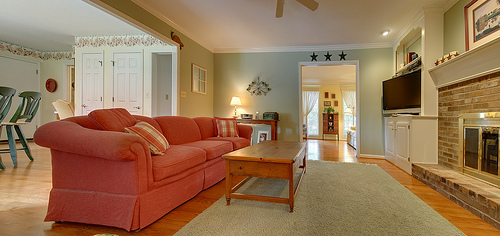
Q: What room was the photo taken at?
A: It was taken at the living room.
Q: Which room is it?
A: It is a living room.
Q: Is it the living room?
A: Yes, it is the living room.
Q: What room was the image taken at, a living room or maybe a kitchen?
A: It was taken at a living room.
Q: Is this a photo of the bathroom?
A: No, the picture is showing the living room.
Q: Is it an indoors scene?
A: Yes, it is indoors.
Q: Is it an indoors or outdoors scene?
A: It is indoors.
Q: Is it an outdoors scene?
A: No, it is indoors.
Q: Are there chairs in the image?
A: Yes, there is a chair.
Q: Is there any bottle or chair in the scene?
A: Yes, there is a chair.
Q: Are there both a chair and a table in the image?
A: Yes, there are both a chair and a table.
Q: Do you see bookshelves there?
A: No, there are no bookshelves.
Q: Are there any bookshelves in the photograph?
A: No, there are no bookshelves.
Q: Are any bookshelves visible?
A: No, there are no bookshelves.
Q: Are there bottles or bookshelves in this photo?
A: No, there are no bookshelves or bottles.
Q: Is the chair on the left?
A: Yes, the chair is on the left of the image.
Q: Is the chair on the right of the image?
A: No, the chair is on the left of the image.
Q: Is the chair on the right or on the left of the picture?
A: The chair is on the left of the image.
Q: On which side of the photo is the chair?
A: The chair is on the left of the image.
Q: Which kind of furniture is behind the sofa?
A: The piece of furniture is a chair.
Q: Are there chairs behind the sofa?
A: Yes, there is a chair behind the sofa.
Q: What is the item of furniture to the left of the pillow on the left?
A: The piece of furniture is a chair.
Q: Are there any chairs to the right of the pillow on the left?
A: No, the chair is to the left of the pillow.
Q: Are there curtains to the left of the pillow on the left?
A: No, there is a chair to the left of the pillow.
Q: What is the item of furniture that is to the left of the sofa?
A: The piece of furniture is a chair.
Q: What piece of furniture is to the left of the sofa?
A: The piece of furniture is a chair.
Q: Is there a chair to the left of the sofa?
A: Yes, there is a chair to the left of the sofa.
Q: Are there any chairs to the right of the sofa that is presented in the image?
A: No, the chair is to the left of the sofa.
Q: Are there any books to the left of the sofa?
A: No, there is a chair to the left of the sofa.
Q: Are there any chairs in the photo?
A: Yes, there is a chair.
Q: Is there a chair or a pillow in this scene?
A: Yes, there is a chair.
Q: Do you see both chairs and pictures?
A: Yes, there are both a chair and a picture.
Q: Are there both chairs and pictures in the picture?
A: Yes, there are both a chair and a picture.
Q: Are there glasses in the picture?
A: No, there are no glasses.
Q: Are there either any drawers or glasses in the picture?
A: No, there are no glasses or drawers.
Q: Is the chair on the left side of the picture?
A: Yes, the chair is on the left of the image.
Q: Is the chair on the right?
A: No, the chair is on the left of the image.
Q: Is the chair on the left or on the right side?
A: The chair is on the left of the image.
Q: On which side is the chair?
A: The chair is on the left of the image.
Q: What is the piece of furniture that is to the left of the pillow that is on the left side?
A: The piece of furniture is a chair.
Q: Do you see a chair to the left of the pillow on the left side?
A: Yes, there is a chair to the left of the pillow.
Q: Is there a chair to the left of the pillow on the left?
A: Yes, there is a chair to the left of the pillow.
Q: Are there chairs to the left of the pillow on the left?
A: Yes, there is a chair to the left of the pillow.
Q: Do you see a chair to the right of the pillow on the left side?
A: No, the chair is to the left of the pillow.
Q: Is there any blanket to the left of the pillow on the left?
A: No, there is a chair to the left of the pillow.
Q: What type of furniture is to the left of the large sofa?
A: The piece of furniture is a chair.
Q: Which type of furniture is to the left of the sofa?
A: The piece of furniture is a chair.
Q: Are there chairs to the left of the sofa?
A: Yes, there is a chair to the left of the sofa.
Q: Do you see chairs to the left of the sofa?
A: Yes, there is a chair to the left of the sofa.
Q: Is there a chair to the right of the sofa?
A: No, the chair is to the left of the sofa.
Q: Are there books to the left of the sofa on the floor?
A: No, there is a chair to the left of the sofa.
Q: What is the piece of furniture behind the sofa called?
A: The piece of furniture is a chair.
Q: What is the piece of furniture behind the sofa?
A: The piece of furniture is a chair.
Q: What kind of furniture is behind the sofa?
A: The piece of furniture is a chair.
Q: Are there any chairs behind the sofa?
A: Yes, there is a chair behind the sofa.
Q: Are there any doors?
A: Yes, there is a door.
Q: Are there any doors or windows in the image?
A: Yes, there is a door.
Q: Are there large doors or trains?
A: Yes, there is a large door.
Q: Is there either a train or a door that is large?
A: Yes, the door is large.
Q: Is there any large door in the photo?
A: Yes, there is a large door.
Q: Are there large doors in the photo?
A: Yes, there is a large door.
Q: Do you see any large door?
A: Yes, there is a large door.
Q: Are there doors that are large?
A: Yes, there is a door that is large.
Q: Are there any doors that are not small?
A: Yes, there is a large door.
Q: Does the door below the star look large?
A: Yes, the door is large.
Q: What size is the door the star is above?
A: The door is large.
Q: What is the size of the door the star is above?
A: The door is large.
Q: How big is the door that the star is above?
A: The door is large.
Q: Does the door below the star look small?
A: No, the door is large.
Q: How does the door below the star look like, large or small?
A: The door is large.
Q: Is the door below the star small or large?
A: The door is large.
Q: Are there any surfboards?
A: No, there are no surfboards.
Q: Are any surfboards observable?
A: No, there are no surfboards.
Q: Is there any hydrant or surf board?
A: No, there are no surfboards or fire hydrants.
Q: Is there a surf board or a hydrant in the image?
A: No, there are no surfboards or fire hydrants.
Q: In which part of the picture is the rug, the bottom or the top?
A: The rug is in the bottom of the image.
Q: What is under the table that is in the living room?
A: The rug is under the table.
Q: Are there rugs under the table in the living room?
A: Yes, there is a rug under the table.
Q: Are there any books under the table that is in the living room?
A: No, there is a rug under the table.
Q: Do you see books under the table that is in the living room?
A: No, there is a rug under the table.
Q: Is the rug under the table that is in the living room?
A: Yes, the rug is under the table.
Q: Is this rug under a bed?
A: No, the rug is under the table.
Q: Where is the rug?
A: The rug is on the floor.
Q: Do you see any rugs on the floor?
A: Yes, there is a rug on the floor.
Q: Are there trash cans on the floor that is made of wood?
A: No, there is a rug on the floor.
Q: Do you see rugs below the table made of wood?
A: Yes, there is a rug below the table.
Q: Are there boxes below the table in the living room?
A: No, there is a rug below the table.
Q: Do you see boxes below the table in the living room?
A: No, there is a rug below the table.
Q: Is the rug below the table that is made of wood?
A: Yes, the rug is below the table.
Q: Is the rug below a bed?
A: No, the rug is below the table.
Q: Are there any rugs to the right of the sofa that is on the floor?
A: Yes, there is a rug to the right of the sofa.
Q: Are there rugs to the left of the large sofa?
A: No, the rug is to the right of the sofa.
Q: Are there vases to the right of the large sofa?
A: No, there is a rug to the right of the sofa.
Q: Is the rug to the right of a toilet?
A: No, the rug is to the right of the sofa.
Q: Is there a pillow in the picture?
A: Yes, there is a pillow.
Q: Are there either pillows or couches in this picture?
A: Yes, there is a pillow.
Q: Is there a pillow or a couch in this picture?
A: Yes, there is a pillow.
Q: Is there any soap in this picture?
A: No, there are no soaps.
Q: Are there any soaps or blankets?
A: No, there are no soaps or blankets.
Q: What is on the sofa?
A: The pillow is on the sofa.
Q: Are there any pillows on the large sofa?
A: Yes, there is a pillow on the sofa.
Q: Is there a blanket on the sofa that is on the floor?
A: No, there is a pillow on the sofa.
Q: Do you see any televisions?
A: Yes, there is a television.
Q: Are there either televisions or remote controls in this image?
A: Yes, there is a television.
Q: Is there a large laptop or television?
A: Yes, there is a large television.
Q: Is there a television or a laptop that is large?
A: Yes, the television is large.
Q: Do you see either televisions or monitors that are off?
A: Yes, the television is off.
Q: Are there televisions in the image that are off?
A: Yes, there is a television that is off.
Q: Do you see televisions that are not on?
A: Yes, there is a television that is off .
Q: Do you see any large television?
A: Yes, there is a large television.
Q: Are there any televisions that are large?
A: Yes, there is a television that is large.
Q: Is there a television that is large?
A: Yes, there is a television that is large.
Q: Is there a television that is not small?
A: Yes, there is a large television.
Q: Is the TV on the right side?
A: Yes, the TV is on the right of the image.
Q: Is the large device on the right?
A: Yes, the TV is on the right of the image.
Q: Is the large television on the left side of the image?
A: No, the television is on the right of the image.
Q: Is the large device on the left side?
A: No, the television is on the right of the image.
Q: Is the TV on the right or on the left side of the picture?
A: The TV is on the right of the image.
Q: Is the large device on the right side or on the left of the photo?
A: The TV is on the right of the image.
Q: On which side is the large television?
A: The television is on the right of the image.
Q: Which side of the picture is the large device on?
A: The television is on the right of the image.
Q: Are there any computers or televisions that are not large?
A: No, there is a television but it is large.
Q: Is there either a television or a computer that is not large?
A: No, there is a television but it is large.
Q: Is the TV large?
A: Yes, the TV is large.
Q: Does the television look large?
A: Yes, the television is large.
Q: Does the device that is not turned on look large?
A: Yes, the television is large.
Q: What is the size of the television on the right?
A: The television is large.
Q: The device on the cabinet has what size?
A: The television is large.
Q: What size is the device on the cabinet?
A: The television is large.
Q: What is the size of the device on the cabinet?
A: The television is large.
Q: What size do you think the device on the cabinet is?
A: The television is large.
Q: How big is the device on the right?
A: The TV is large.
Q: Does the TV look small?
A: No, the TV is large.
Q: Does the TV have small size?
A: No, the TV is large.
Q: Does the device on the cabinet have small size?
A: No, the TV is large.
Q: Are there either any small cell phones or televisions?
A: No, there is a television but it is large.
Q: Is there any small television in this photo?
A: No, there is a television but it is large.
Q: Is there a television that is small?
A: No, there is a television but it is large.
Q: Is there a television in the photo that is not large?
A: No, there is a television but it is large.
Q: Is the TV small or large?
A: The TV is large.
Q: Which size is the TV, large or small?
A: The TV is large.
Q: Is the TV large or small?
A: The TV is large.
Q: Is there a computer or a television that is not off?
A: No, there is a television but it is off.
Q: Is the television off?
A: Yes, the television is off.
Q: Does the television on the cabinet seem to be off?
A: Yes, the television is off.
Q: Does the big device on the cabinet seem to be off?
A: Yes, the television is off.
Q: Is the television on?
A: No, the television is off.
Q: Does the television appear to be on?
A: No, the television is off.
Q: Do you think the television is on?
A: No, the television is off.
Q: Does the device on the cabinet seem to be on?
A: No, the television is off.